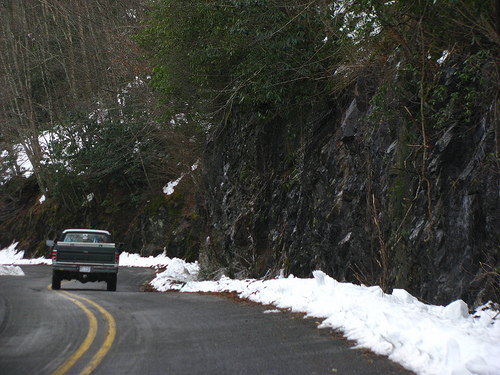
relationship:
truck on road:
[50, 224, 122, 290] [2, 256, 415, 374]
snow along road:
[166, 264, 499, 374] [2, 256, 415, 374]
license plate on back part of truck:
[77, 268, 94, 277] [50, 224, 122, 290]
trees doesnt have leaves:
[1, 5, 146, 163] [1, 0, 149, 175]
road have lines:
[2, 256, 415, 374] [47, 276, 115, 374]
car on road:
[50, 224, 122, 290] [2, 256, 415, 374]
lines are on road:
[47, 276, 115, 374] [2, 256, 415, 374]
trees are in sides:
[132, 10, 496, 287] [127, 245, 497, 368]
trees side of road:
[132, 10, 496, 287] [2, 256, 415, 374]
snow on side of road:
[166, 264, 499, 374] [2, 256, 415, 374]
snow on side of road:
[1, 235, 57, 262] [2, 256, 415, 374]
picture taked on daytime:
[1, 4, 499, 367] [3, 3, 499, 367]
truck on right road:
[50, 224, 122, 290] [61, 252, 406, 374]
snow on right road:
[166, 264, 499, 374] [61, 252, 406, 374]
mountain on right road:
[132, 10, 496, 287] [61, 252, 406, 374]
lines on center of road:
[47, 276, 115, 374] [2, 256, 415, 374]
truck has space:
[50, 224, 122, 290] [56, 243, 114, 276]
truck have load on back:
[50, 224, 122, 290] [56, 231, 124, 279]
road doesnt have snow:
[2, 256, 415, 374] [9, 246, 391, 373]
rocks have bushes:
[195, 59, 499, 303] [132, 10, 496, 287]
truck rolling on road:
[50, 224, 122, 290] [2, 256, 415, 374]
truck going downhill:
[50, 224, 122, 290] [5, 226, 187, 277]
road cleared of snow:
[2, 256, 415, 374] [1, 235, 57, 262]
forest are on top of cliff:
[7, 8, 496, 290] [1, 1, 214, 224]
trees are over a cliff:
[1, 5, 146, 163] [1, 1, 214, 224]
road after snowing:
[2, 256, 415, 374] [9, 246, 391, 373]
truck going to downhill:
[50, 224, 122, 290] [5, 226, 187, 277]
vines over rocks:
[374, 107, 422, 280] [195, 59, 499, 303]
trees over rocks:
[132, 10, 496, 287] [195, 59, 499, 303]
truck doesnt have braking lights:
[50, 224, 122, 290] [48, 249, 123, 269]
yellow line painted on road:
[46, 276, 117, 374] [2, 256, 415, 374]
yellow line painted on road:
[81, 291, 114, 374] [2, 256, 415, 374]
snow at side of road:
[166, 264, 499, 374] [2, 256, 415, 374]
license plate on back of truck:
[77, 268, 94, 277] [50, 224, 122, 290]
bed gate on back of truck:
[56, 231, 124, 279] [50, 224, 122, 290]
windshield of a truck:
[59, 229, 110, 245] [50, 224, 122, 290]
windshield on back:
[59, 229, 110, 245] [56, 231, 124, 279]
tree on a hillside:
[149, 2, 340, 257] [15, 3, 495, 295]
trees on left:
[1, 5, 146, 163] [6, 1, 71, 240]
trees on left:
[38, 107, 118, 251] [6, 1, 71, 240]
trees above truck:
[1, 5, 146, 163] [50, 224, 122, 290]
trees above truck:
[38, 107, 118, 251] [50, 224, 122, 290]